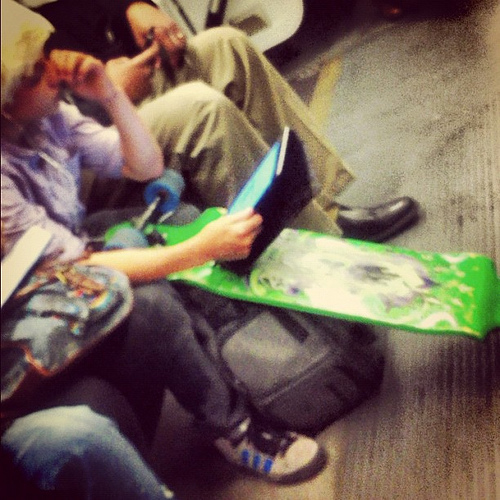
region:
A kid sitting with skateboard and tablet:
[4, 27, 499, 350]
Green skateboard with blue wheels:
[114, 170, 496, 341]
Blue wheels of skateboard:
[88, 159, 194, 264]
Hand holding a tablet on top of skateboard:
[190, 120, 317, 291]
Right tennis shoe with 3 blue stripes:
[189, 410, 339, 486]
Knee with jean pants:
[10, 388, 186, 498]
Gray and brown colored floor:
[361, 50, 486, 191]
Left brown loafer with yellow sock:
[318, 188, 423, 240]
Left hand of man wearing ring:
[116, 5, 194, 79]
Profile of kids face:
[2, 14, 166, 185]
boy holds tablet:
[219, 125, 309, 241]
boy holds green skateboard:
[133, 209, 488, 341]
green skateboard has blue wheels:
[66, 168, 176, 266]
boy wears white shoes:
[155, 381, 330, 486]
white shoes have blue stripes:
[208, 423, 323, 488]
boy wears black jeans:
[118, 239, 235, 439]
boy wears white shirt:
[2, 110, 166, 205]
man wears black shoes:
[328, 181, 420, 237]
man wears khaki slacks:
[116, 6, 390, 158]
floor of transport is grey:
[317, 81, 477, 256]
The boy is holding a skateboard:
[101, 168, 483, 354]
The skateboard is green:
[105, 173, 453, 353]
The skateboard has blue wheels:
[105, 171, 192, 262]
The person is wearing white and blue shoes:
[216, 408, 334, 497]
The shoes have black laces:
[218, 415, 320, 491]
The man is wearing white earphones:
[10, 75, 107, 234]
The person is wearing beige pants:
[115, 39, 358, 226]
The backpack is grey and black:
[161, 250, 376, 443]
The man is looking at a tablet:
[10, 41, 307, 281]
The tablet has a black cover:
[208, 111, 329, 262]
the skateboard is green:
[93, 192, 499, 345]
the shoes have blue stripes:
[239, 447, 276, 483]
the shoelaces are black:
[238, 413, 299, 462]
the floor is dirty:
[138, 1, 498, 498]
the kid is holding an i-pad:
[216, 123, 323, 280]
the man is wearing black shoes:
[326, 190, 423, 247]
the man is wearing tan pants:
[80, 20, 357, 240]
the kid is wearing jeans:
[36, 202, 262, 435]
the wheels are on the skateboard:
[92, 201, 498, 358]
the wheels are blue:
[95, 167, 200, 270]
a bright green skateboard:
[93, 170, 498, 345]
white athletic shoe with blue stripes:
[209, 413, 324, 485]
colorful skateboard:
[5, 251, 138, 387]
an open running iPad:
[207, 119, 309, 276]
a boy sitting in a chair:
[1, 14, 374, 478]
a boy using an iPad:
[2, 10, 330, 476]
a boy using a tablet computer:
[4, 8, 350, 490]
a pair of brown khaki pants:
[121, 19, 352, 247]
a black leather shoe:
[332, 196, 423, 242]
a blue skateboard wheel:
[141, 166, 181, 211]